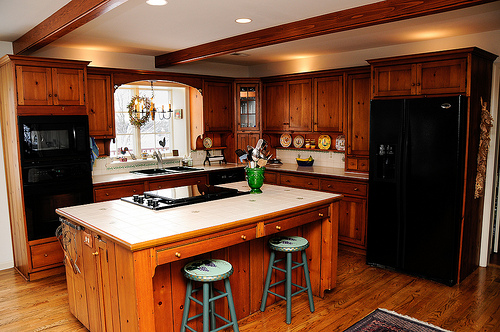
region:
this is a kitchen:
[27, 87, 242, 275]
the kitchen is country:
[49, 149, 248, 316]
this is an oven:
[30, 107, 134, 202]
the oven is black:
[23, 122, 98, 243]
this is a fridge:
[427, 126, 441, 246]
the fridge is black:
[333, 119, 420, 306]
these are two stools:
[182, 251, 400, 304]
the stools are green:
[200, 241, 252, 304]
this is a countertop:
[115, 193, 151, 265]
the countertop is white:
[104, 222, 146, 281]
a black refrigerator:
[321, 75, 493, 329]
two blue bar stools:
[163, 240, 337, 330]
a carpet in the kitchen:
[327, 302, 432, 330]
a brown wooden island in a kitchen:
[38, 178, 333, 330]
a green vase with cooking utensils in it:
[223, 130, 287, 200]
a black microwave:
[9, 98, 100, 168]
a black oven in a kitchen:
[20, 160, 133, 254]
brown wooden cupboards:
[246, 67, 458, 164]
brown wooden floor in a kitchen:
[326, 243, 494, 328]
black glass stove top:
[102, 175, 247, 223]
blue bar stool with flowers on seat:
[259, 229, 317, 322]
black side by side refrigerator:
[360, 93, 480, 288]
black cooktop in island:
[124, 181, 247, 212]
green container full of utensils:
[233, 134, 276, 194]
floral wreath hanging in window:
[127, 93, 152, 126]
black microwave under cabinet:
[17, 112, 89, 174]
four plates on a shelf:
[276, 130, 347, 151]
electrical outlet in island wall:
[75, 228, 97, 247]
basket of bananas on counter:
[293, 152, 315, 169]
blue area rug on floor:
[320, 305, 451, 330]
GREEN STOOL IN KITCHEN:
[173, 257, 221, 323]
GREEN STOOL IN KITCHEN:
[267, 231, 327, 305]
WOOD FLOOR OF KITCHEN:
[329, 266, 416, 315]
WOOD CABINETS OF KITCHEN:
[47, 218, 291, 328]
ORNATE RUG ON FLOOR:
[342, 295, 377, 322]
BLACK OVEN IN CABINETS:
[19, 109, 85, 220]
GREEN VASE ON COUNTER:
[241, 141, 277, 188]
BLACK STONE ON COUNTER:
[130, 163, 232, 214]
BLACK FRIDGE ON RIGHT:
[393, 81, 450, 252]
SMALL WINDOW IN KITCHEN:
[232, 75, 265, 140]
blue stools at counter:
[268, 235, 316, 325]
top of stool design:
[277, 231, 309, 251]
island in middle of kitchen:
[57, 162, 337, 330]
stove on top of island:
[120, 179, 234, 219]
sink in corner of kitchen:
[149, 155, 194, 179]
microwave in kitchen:
[18, 113, 92, 150]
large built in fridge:
[364, 91, 466, 283]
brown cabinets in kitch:
[261, 79, 336, 134]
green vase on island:
[242, 165, 266, 197]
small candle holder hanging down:
[141, 100, 174, 119]